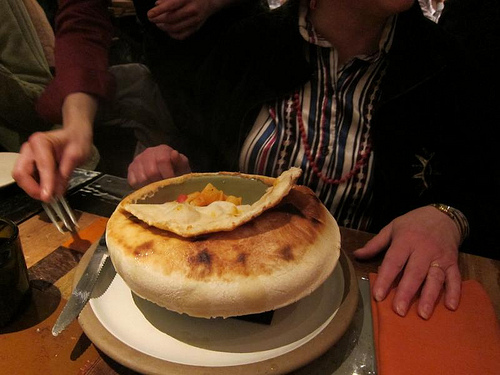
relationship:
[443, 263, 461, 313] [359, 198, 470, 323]
finger on hand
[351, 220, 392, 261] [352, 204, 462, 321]
finger on hand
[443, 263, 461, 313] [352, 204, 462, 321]
finger on hand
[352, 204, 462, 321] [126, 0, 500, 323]
hand on woman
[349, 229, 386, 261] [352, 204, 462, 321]
finger on hand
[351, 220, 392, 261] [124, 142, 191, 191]
finger on hand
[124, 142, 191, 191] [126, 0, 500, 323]
hand on woman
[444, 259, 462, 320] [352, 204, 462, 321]
finger on hand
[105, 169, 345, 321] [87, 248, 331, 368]
meal on plate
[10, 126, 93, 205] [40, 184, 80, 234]
hand holding fork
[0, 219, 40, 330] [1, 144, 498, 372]
glass on table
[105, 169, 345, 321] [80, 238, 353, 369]
meal on plate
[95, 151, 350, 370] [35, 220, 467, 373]
meal on plate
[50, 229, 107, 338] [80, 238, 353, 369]
knife on plate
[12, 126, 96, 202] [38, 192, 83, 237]
hand holding fork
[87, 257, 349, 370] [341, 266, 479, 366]
plate on table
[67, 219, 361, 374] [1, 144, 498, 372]
plate on table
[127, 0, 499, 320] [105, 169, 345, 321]
woman about to eat meal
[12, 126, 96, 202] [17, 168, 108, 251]
hand holding fork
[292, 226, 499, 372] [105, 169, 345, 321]
table with meal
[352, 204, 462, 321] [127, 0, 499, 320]
hand of woman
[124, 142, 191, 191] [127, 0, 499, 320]
hand of woman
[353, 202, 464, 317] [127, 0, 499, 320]
hand of woman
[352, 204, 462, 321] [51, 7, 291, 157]
hand of woman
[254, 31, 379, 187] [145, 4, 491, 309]
necklace worn by woman